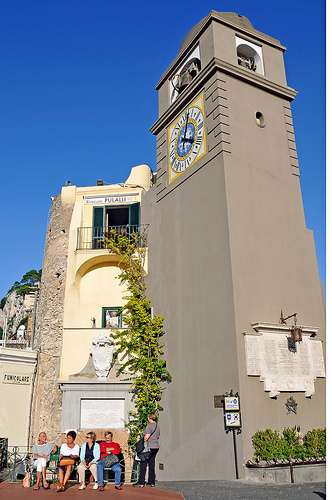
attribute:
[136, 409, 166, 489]
woman — standing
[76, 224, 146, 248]
railing — metal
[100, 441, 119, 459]
shirt — red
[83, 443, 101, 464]
sweater — light-blue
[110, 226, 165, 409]
vine — long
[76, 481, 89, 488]
white shoe — white 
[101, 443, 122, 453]
red shirt — red 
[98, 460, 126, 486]
blue jeans — blue 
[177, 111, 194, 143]
black hands — black 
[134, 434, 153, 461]
large bag — large 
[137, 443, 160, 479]
black pants — black 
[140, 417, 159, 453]
grey top — grey 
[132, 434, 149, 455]
crossbody bag — black, dark blue, grey 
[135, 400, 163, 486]
woman — blonde 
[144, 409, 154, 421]
blonde hair — short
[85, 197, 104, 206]
word — blurry 